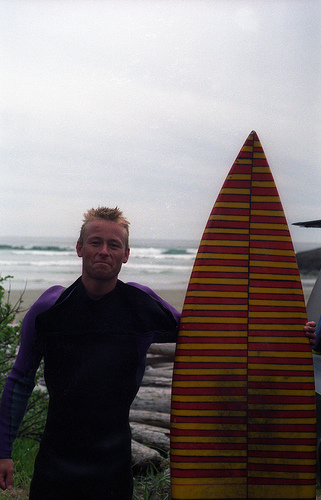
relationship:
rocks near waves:
[3, 243, 194, 260] [5, 251, 195, 276]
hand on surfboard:
[302, 321, 320, 352] [177, 131, 317, 500]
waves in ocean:
[5, 251, 195, 276] [2, 237, 198, 296]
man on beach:
[1, 204, 186, 497] [3, 286, 320, 500]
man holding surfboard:
[1, 204, 186, 497] [177, 131, 317, 500]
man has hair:
[1, 204, 186, 497] [77, 205, 133, 226]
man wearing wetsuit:
[1, 204, 186, 497] [1, 278, 179, 498]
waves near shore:
[5, 251, 195, 276] [1, 283, 183, 297]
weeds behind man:
[1, 272, 50, 461] [1, 204, 186, 497]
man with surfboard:
[1, 204, 186, 497] [177, 131, 317, 500]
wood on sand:
[130, 339, 175, 493] [3, 278, 195, 314]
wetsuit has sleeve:
[1, 278, 179, 498] [1, 276, 59, 453]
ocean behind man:
[2, 237, 198, 296] [1, 204, 186, 497]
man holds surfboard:
[1, 204, 186, 497] [177, 131, 317, 500]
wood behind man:
[130, 339, 175, 493] [1, 204, 186, 497]